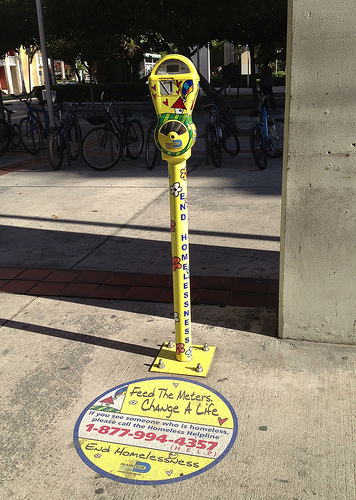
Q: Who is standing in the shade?
A: A man.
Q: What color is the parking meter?
A: Yellow.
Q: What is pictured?
A: A parking meter.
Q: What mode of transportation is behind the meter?
A: Bikes.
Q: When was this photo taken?
A: Daytime.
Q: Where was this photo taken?
A: Sidewalk.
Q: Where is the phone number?
A: On the ground.